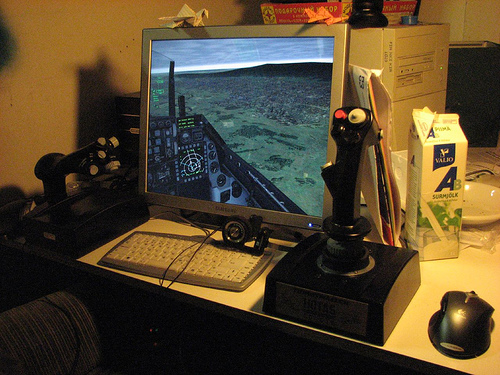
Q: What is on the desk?
A: A computer monitor?.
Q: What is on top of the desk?
A: A computer keyboard.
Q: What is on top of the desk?
A: A game controller.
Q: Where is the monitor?
A: On the desk.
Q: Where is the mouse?
A: Right of joystick.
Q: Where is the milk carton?
A: On the desk.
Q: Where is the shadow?
A: On the wall.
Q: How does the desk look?
A: White.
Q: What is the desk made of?
A: Wood.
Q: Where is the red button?
A: On the joystick.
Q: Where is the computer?
A: On the desk.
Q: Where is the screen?
A: On the desk.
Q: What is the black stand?
A: A controller.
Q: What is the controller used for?
A: Gaming.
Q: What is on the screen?
A: A game.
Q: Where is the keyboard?
A: In front of the monitor.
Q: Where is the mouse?
A: By the controller.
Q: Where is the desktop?
A: In an office.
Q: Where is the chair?
A: IN front of the desk.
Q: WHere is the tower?
A: On the desk.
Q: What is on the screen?
A: A game.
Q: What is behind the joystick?
A: A carton.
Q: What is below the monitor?
A: A keyboard.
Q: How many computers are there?
A: One.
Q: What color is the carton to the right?
A: White.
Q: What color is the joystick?
A: Black.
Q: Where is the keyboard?
A: Below the monitor.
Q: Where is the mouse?
A: Beside the joystick.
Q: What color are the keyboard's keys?
A: White.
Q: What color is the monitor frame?
A: Silver.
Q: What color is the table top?
A: White.